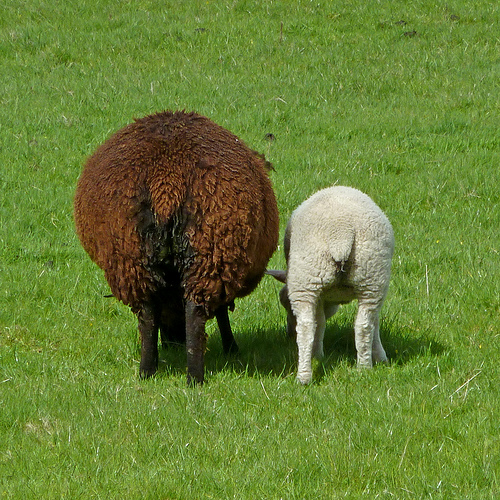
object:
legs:
[355, 293, 376, 371]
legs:
[292, 295, 314, 384]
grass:
[7, 1, 494, 494]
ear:
[264, 269, 287, 283]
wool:
[87, 122, 259, 294]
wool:
[297, 204, 376, 259]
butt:
[100, 111, 261, 309]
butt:
[288, 185, 394, 295]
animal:
[74, 107, 278, 387]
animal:
[264, 183, 395, 386]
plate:
[291, 199, 383, 297]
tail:
[328, 240, 354, 272]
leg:
[137, 297, 160, 379]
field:
[0, 0, 499, 498]